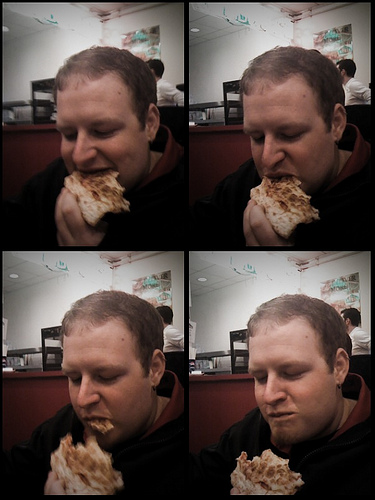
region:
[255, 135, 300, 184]
the nose of a man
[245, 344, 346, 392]
the eyes of a man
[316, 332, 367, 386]
the ear of a man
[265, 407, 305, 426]
the lips of a man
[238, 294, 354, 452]
the face of a man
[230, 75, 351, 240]
a man eating pizza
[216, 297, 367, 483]
a man wearing a shirt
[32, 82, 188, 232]
a man biting a pizza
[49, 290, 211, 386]
the hair of a man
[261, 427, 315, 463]
the chin of a man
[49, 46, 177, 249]
a man taking a bite of pizza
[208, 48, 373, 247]
a man taking a bite of pizza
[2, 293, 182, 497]
a man chewing pizza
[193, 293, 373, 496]
a man chewing pizza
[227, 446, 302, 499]
a slice of pizza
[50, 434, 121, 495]
a slice of pizza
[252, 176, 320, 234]
a slice of pizza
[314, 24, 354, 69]
a poster on a wall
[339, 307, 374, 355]
a man in white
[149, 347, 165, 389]
ear of a man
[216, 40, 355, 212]
the head of a man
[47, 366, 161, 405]
the eyes of a man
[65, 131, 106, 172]
the nose of a man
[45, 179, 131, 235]
the hand of a man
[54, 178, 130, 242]
the fingers of a man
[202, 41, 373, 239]
a man wearing a shirt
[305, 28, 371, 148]
a man in the background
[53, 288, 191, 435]
the face of a man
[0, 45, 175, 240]
a man eating food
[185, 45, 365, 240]
a man eating food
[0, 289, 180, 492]
a man eating food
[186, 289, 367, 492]
a man eating food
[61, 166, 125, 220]
a brown piece of bread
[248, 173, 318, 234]
a brown piece of bread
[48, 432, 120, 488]
a brown piece of bread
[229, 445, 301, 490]
a brown piece of bread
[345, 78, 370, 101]
a man's white shirt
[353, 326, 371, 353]
a man's white shirt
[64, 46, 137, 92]
Man has brown hair.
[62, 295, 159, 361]
Man has short hair.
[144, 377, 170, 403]
Man wearing earring in ear.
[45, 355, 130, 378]
Man has light eyebrows.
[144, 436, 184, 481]
Person wearing dark shirt.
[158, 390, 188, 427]
Red collar on shirt.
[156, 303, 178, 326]
Person has dark hair.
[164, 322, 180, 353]
Person wearing white shirt.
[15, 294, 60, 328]
Wall is painted white.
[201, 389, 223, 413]
Person behind red counter.